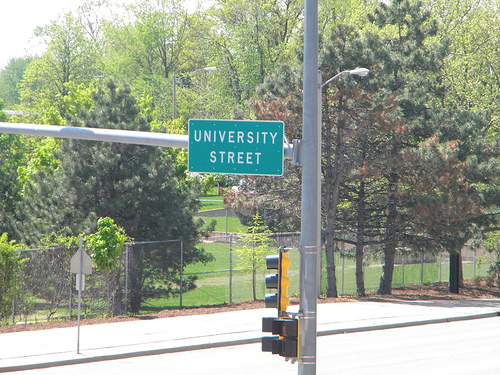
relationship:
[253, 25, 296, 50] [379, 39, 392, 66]
tree have leaves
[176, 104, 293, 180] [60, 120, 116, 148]
street sign on pole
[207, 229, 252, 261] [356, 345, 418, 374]
fence by street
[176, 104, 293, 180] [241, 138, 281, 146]
street sign has white letters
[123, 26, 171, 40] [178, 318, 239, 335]
trees by sidewalk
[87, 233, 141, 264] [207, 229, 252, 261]
ivy on fence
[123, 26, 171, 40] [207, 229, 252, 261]
trees behind fence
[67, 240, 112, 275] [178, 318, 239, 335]
school sign on sidewalk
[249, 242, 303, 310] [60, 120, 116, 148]
traffic light on pole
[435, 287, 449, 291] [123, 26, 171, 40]
pinstraw under trees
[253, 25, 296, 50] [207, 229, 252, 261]
tree behind fence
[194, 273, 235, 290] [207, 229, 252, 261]
walking track behind fence